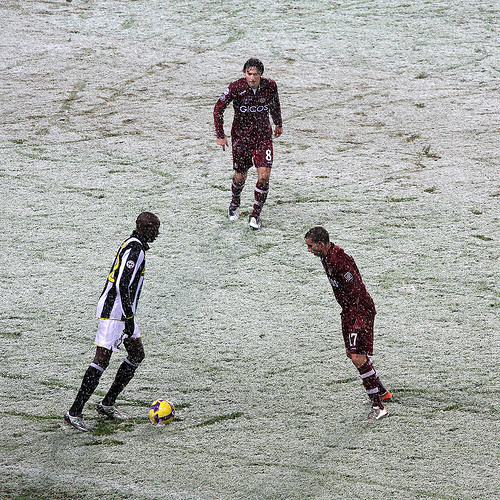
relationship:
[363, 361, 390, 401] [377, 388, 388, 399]
sock has stripe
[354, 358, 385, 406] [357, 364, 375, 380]
sock has stripe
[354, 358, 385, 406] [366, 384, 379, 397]
sock has stripe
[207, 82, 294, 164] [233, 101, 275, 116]
shirt has letters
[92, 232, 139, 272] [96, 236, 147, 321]
print on jersey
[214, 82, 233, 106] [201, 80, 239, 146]
logo on sleeve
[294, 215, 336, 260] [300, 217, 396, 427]
head of man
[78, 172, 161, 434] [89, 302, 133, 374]
man wearing shorts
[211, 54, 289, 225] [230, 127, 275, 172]
man wearing shorts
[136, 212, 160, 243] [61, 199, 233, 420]
head of man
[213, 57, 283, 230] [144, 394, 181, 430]
man playing soccer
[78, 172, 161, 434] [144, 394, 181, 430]
man playing soccer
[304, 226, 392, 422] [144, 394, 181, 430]
man playing soccer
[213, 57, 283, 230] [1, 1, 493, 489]
man playing soccer in snow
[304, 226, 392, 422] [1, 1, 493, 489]
man playing soccer in snow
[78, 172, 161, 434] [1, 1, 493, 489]
man playing soccer in snow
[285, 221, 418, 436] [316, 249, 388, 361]
man wearing uniform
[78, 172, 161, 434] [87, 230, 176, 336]
man wearing uniform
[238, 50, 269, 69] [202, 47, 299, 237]
hair of man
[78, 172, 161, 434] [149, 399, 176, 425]
man playing ball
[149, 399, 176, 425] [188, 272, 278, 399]
ball in snow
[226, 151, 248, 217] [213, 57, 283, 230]
leg of a man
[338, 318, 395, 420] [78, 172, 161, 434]
legs of a man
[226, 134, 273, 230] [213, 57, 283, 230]
legs of a man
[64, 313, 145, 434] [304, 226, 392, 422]
legs of a man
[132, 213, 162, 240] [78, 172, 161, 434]
head of a man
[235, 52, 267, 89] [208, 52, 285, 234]
head of a man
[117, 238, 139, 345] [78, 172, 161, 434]
arm of a man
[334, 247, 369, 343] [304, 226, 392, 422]
arm of a man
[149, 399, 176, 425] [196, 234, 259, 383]
ball in snow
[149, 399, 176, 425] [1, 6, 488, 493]
ball in rain